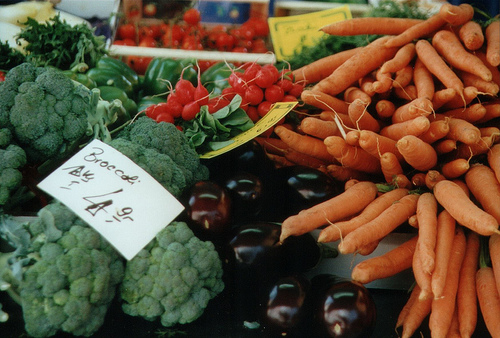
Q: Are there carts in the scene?
A: No, there are no carts.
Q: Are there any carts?
A: No, there are no carts.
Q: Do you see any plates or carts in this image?
A: No, there are no carts or plates.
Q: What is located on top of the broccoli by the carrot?
A: The paper is on top of the broccoli.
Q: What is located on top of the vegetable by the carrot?
A: The paper is on top of the broccoli.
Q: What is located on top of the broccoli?
A: The paper is on top of the broccoli.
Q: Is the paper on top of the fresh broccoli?
A: Yes, the paper is on top of the broccoli.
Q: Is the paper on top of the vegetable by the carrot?
A: Yes, the paper is on top of the broccoli.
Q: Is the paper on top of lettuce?
A: No, the paper is on top of the broccoli.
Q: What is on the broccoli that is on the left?
A: The paper is on the broccoli.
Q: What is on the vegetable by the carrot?
A: The paper is on the broccoli.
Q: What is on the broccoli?
A: The paper is on the broccoli.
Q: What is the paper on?
A: The paper is on the broccoli.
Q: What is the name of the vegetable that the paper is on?
A: The vegetable is broccoli.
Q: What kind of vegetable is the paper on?
A: The paper is on the broccoli.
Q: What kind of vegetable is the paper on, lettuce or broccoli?
A: The paper is on broccoli.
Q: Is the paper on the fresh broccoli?
A: Yes, the paper is on the broccoli.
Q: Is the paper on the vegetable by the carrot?
A: Yes, the paper is on the broccoli.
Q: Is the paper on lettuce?
A: No, the paper is on the broccoli.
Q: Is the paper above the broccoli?
A: Yes, the paper is above the broccoli.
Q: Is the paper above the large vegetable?
A: Yes, the paper is above the broccoli.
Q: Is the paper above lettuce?
A: No, the paper is above the broccoli.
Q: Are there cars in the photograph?
A: No, there are no cars.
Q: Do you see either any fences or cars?
A: No, there are no cars or fences.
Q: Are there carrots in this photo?
A: Yes, there is a carrot.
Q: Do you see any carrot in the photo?
A: Yes, there is a carrot.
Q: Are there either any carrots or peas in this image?
A: Yes, there is a carrot.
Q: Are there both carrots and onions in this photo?
A: No, there is a carrot but no onions.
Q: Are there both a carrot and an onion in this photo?
A: No, there is a carrot but no onions.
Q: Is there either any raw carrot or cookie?
A: Yes, there is a raw carrot.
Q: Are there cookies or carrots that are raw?
A: Yes, the carrot is raw.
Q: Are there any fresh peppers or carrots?
A: Yes, there is a fresh carrot.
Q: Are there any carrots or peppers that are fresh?
A: Yes, the carrot is fresh.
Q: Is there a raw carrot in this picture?
A: Yes, there is a raw carrot.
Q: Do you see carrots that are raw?
A: Yes, there is a carrot that is raw.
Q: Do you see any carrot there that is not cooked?
A: Yes, there is a raw carrot.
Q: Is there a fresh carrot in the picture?
A: Yes, there is a fresh carrot.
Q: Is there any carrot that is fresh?
A: Yes, there is a carrot that is fresh.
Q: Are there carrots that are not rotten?
A: Yes, there is a fresh carrot.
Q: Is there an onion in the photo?
A: No, there are no onions.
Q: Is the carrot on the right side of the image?
A: Yes, the carrot is on the right of the image.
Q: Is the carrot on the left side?
A: No, the carrot is on the right of the image.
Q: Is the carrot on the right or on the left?
A: The carrot is on the right of the image.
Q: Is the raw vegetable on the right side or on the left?
A: The carrot is on the right of the image.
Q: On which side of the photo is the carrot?
A: The carrot is on the right of the image.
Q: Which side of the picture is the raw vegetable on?
A: The carrot is on the right of the image.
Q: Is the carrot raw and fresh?
A: Yes, the carrot is raw and fresh.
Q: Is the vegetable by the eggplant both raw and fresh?
A: Yes, the carrot is raw and fresh.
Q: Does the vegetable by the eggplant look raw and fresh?
A: Yes, the carrot is raw and fresh.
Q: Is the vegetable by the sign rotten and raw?
A: No, the carrot is raw but fresh.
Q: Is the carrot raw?
A: Yes, the carrot is raw.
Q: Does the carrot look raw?
A: Yes, the carrot is raw.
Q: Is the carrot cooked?
A: No, the carrot is raw.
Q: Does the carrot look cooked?
A: No, the carrot is raw.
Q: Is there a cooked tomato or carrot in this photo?
A: No, there is a carrot but it is raw.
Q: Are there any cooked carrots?
A: No, there is a carrot but it is raw.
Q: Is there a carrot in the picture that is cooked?
A: No, there is a carrot but it is raw.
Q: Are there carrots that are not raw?
A: No, there is a carrot but it is raw.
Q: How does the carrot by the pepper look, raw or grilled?
A: The carrot is raw.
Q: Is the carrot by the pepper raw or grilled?
A: The carrot is raw.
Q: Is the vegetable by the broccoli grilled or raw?
A: The carrot is raw.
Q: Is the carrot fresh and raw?
A: Yes, the carrot is fresh and raw.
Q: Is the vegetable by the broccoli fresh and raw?
A: Yes, the carrot is fresh and raw.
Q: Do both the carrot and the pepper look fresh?
A: Yes, both the carrot and the pepper are fresh.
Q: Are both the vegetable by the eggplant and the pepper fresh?
A: Yes, both the carrot and the pepper are fresh.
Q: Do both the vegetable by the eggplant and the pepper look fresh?
A: Yes, both the carrot and the pepper are fresh.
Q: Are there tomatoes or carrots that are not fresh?
A: No, there is a carrot but it is fresh.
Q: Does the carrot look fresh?
A: Yes, the carrot is fresh.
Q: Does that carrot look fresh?
A: Yes, the carrot is fresh.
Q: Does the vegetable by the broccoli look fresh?
A: Yes, the carrot is fresh.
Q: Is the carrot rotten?
A: No, the carrot is fresh.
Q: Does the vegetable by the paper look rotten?
A: No, the carrot is fresh.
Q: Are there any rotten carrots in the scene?
A: No, there is a carrot but it is fresh.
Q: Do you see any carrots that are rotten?
A: No, there is a carrot but it is fresh.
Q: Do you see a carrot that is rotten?
A: No, there is a carrot but it is fresh.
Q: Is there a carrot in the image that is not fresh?
A: No, there is a carrot but it is fresh.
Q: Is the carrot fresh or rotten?
A: The carrot is fresh.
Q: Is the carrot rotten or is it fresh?
A: The carrot is fresh.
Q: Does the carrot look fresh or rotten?
A: The carrot is fresh.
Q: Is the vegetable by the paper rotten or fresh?
A: The carrot is fresh.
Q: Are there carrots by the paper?
A: Yes, there is a carrot by the paper.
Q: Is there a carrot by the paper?
A: Yes, there is a carrot by the paper.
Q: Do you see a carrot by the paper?
A: Yes, there is a carrot by the paper.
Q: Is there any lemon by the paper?
A: No, there is a carrot by the paper.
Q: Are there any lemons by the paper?
A: No, there is a carrot by the paper.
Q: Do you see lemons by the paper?
A: No, there is a carrot by the paper.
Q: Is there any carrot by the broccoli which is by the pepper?
A: Yes, there is a carrot by the broccoli.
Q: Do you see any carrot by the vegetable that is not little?
A: Yes, there is a carrot by the broccoli.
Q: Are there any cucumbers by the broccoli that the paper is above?
A: No, there is a carrot by the broccoli.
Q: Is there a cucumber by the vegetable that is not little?
A: No, there is a carrot by the broccoli.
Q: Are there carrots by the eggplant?
A: Yes, there is a carrot by the eggplant.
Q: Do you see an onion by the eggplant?
A: No, there is a carrot by the eggplant.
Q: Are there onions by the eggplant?
A: No, there is a carrot by the eggplant.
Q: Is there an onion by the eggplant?
A: No, there is a carrot by the eggplant.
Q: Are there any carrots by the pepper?
A: Yes, there is a carrot by the pepper.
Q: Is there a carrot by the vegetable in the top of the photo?
A: Yes, there is a carrot by the pepper.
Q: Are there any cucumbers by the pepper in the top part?
A: No, there is a carrot by the pepper.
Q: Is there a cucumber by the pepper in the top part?
A: No, there is a carrot by the pepper.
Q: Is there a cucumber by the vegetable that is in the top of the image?
A: No, there is a carrot by the pepper.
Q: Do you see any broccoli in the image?
A: Yes, there is broccoli.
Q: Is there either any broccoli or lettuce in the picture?
A: Yes, there is broccoli.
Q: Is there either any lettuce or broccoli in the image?
A: Yes, there is broccoli.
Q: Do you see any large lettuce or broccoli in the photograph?
A: Yes, there is large broccoli.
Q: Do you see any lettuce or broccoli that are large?
A: Yes, the broccoli is large.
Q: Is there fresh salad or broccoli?
A: Yes, there is fresh broccoli.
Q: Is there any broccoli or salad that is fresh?
A: Yes, the broccoli is fresh.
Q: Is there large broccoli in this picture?
A: Yes, there is large broccoli.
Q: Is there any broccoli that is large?
A: Yes, there is broccoli that is large.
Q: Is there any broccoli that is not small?
A: Yes, there is large broccoli.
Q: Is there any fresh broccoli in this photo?
A: Yes, there is fresh broccoli.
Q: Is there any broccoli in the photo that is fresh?
A: Yes, there is broccoli that is fresh.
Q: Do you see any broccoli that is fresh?
A: Yes, there is broccoli that is fresh.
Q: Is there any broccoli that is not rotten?
A: Yes, there is fresh broccoli.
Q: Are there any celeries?
A: No, there are no celeries.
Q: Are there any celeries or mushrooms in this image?
A: No, there are no celeries or mushrooms.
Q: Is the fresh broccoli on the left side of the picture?
A: Yes, the broccoli is on the left of the image.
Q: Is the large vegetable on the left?
A: Yes, the broccoli is on the left of the image.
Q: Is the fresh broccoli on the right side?
A: No, the broccoli is on the left of the image.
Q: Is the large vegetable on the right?
A: No, the broccoli is on the left of the image.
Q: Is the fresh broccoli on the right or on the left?
A: The broccoli is on the left of the image.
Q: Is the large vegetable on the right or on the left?
A: The broccoli is on the left of the image.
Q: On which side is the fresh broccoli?
A: The broccoli is on the left of the image.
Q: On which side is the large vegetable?
A: The broccoli is on the left of the image.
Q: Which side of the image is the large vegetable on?
A: The broccoli is on the left of the image.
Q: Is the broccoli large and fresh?
A: Yes, the broccoli is large and fresh.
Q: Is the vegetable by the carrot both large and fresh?
A: Yes, the broccoli is large and fresh.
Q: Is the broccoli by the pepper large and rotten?
A: No, the broccoli is large but fresh.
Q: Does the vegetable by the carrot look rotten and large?
A: No, the broccoli is large but fresh.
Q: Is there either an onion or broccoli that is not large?
A: No, there is broccoli but it is large.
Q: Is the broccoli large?
A: Yes, the broccoli is large.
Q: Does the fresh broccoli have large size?
A: Yes, the broccoli is large.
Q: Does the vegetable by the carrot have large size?
A: Yes, the broccoli is large.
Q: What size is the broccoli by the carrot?
A: The broccoli is large.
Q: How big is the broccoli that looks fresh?
A: The broccoli is large.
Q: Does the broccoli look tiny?
A: No, the broccoli is large.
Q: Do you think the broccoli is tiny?
A: No, the broccoli is large.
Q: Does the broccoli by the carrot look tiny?
A: No, the broccoli is large.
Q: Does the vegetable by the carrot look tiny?
A: No, the broccoli is large.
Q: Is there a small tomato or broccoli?
A: No, there is broccoli but it is large.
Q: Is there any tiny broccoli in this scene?
A: No, there is broccoli but it is large.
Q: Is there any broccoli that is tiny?
A: No, there is broccoli but it is large.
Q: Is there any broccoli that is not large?
A: No, there is broccoli but it is large.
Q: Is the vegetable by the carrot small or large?
A: The broccoli is large.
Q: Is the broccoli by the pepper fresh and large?
A: Yes, the broccoli is fresh and large.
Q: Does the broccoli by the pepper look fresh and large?
A: Yes, the broccoli is fresh and large.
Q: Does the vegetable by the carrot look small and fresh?
A: No, the broccoli is fresh but large.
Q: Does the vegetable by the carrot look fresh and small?
A: No, the broccoli is fresh but large.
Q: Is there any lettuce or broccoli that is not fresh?
A: No, there is broccoli but it is fresh.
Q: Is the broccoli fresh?
A: Yes, the broccoli is fresh.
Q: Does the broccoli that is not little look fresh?
A: Yes, the broccoli is fresh.